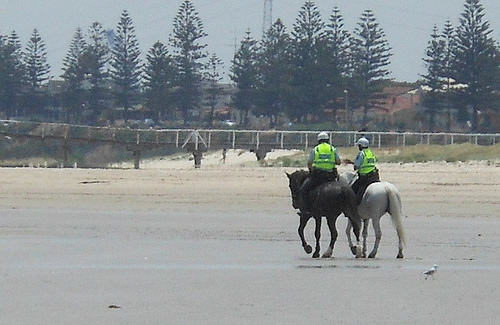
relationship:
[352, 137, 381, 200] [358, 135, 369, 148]
person wearing a helmet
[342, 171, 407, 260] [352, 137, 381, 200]
horse carrying a person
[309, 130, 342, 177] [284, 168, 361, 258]
police officer riding a horse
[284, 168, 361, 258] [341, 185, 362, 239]
horse has a tail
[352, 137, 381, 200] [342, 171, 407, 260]
person riding a horse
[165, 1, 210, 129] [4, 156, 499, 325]
tree by beach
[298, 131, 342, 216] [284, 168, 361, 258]
police officer riding a horse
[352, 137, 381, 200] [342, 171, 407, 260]
person on a horse